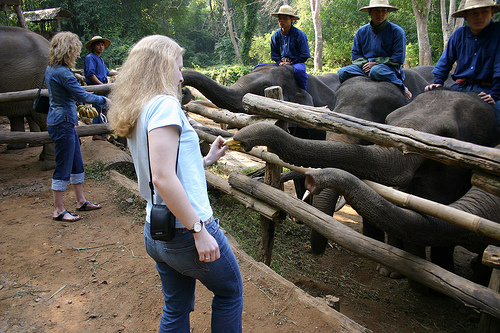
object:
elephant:
[221, 85, 500, 258]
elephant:
[303, 64, 446, 255]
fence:
[188, 86, 499, 328]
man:
[337, 0, 416, 101]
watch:
[188, 219, 204, 234]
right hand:
[193, 230, 223, 264]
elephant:
[182, 63, 355, 173]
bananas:
[89, 107, 99, 117]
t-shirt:
[123, 96, 214, 227]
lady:
[109, 34, 242, 331]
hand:
[203, 135, 229, 168]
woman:
[38, 26, 120, 226]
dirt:
[0, 164, 140, 333]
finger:
[204, 250, 212, 263]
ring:
[205, 257, 211, 261]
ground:
[0, 154, 431, 332]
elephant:
[1, 23, 65, 171]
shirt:
[268, 27, 311, 61]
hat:
[353, 0, 403, 13]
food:
[220, 139, 243, 153]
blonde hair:
[103, 34, 187, 138]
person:
[424, 0, 500, 111]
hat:
[448, 0, 497, 19]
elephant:
[304, 139, 500, 252]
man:
[253, 5, 315, 91]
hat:
[271, 4, 300, 21]